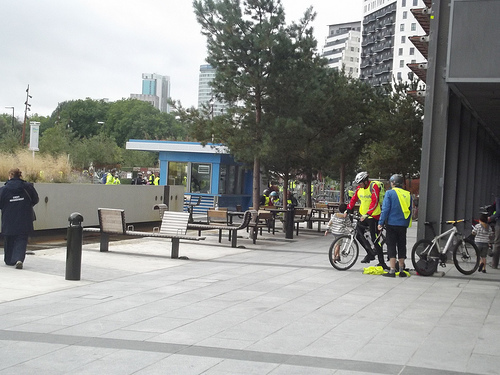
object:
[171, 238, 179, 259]
pole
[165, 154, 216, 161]
blue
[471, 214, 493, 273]
person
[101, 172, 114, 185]
jacket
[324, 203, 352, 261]
person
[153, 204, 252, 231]
benches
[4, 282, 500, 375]
ground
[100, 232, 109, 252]
pole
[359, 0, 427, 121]
building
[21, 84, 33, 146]
poles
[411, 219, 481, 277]
bicycle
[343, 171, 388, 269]
man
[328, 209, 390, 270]
bicyclist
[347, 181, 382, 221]
jacket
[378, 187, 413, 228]
jacket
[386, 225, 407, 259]
pants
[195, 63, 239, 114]
building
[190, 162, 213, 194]
window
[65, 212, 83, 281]
pole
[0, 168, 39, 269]
person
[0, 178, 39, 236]
jacket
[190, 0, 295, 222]
tree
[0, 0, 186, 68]
sky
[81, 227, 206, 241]
bench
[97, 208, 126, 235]
backrest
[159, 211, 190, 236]
backrest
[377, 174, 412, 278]
man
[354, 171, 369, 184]
helmet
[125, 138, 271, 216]
cabin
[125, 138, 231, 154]
roof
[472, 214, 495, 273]
girl